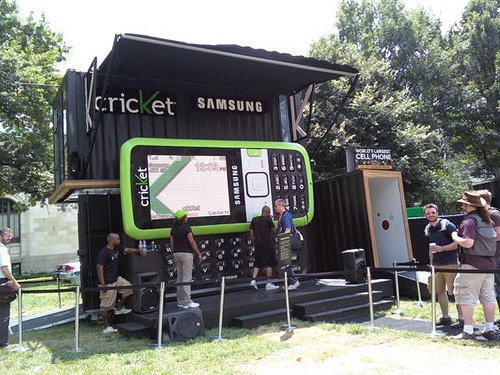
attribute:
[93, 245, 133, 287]
shirt — black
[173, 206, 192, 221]
cap — green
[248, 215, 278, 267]
clothes — black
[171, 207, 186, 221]
bandana — green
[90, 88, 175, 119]
sign — black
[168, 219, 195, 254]
shirt — black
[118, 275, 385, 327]
stage — black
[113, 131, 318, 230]
cellphone — large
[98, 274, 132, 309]
pants — khaki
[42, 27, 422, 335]
phone shop — black